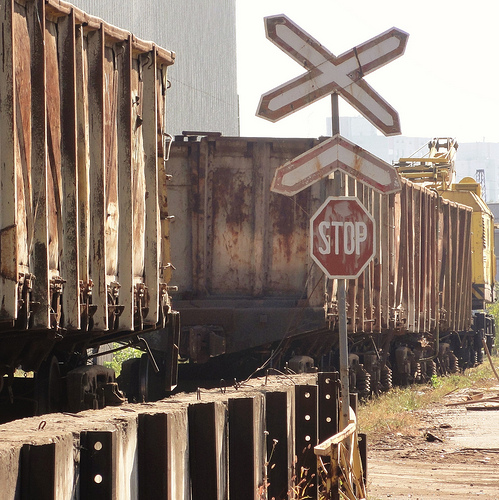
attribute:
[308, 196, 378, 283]
stop sign — dirty, red, white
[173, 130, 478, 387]
box — rusty, metal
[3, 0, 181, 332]
box — rusty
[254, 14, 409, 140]
sign — x shaped, red, white, cross shaped, crossing sign, for trains, railway crossing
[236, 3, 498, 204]
sky — white, cloudy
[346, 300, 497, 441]
grass — long, green, short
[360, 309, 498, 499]
ground — dusty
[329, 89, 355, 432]
pole — metal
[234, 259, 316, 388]
wire — metal, sticking out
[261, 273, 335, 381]
wire — metal, sticking out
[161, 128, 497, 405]
train — dirty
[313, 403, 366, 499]
fence — metal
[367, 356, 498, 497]
road — crumbling, small, dirt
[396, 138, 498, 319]
machine — yellow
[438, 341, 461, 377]
wheel — rusty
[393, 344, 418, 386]
wheel — rusty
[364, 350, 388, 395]
wheel — rusty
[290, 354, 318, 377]
wheel — rusty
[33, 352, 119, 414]
wheel — rusty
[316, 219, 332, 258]
letter — white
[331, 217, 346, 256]
letter — white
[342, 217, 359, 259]
letter — white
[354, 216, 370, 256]
letter — white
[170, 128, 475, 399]
train car — metal, rusty, old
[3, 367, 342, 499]
wall — cement, small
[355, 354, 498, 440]
patch — grass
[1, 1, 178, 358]
container — old